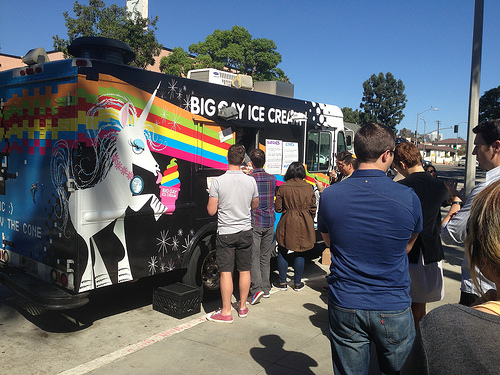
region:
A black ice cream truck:
[12, 48, 365, 317]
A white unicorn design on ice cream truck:
[44, 70, 173, 290]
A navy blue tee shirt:
[320, 164, 422, 321]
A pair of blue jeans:
[322, 300, 414, 374]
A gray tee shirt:
[214, 156, 254, 232]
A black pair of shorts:
[212, 230, 260, 275]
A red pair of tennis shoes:
[210, 301, 253, 327]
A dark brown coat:
[280, 176, 321, 257]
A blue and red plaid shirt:
[252, 170, 277, 231]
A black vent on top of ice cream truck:
[66, 29, 136, 62]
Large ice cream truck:
[9, 46, 361, 307]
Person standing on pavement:
[211, 126, 254, 327]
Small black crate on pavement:
[143, 276, 206, 324]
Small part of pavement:
[72, 334, 127, 371]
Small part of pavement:
[150, 342, 165, 358]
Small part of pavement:
[215, 349, 233, 371]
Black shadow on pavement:
[242, 323, 294, 374]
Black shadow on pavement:
[300, 294, 339, 340]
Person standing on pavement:
[321, 126, 420, 369]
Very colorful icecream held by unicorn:
[56, 82, 191, 299]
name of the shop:
[157, 83, 324, 131]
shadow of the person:
[247, 330, 316, 360]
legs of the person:
[206, 284, 279, 336]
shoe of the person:
[198, 300, 240, 328]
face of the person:
[341, 117, 411, 174]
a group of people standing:
[24, 62, 496, 372]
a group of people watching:
[178, 128, 340, 334]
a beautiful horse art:
[61, 106, 174, 297]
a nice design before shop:
[46, 83, 201, 287]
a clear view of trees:
[202, 30, 426, 141]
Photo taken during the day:
[32, 11, 484, 373]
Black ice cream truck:
[8, 73, 351, 303]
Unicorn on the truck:
[60, 75, 175, 305]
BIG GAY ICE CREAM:
[182, 85, 304, 140]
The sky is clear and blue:
[12, 0, 469, 137]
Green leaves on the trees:
[99, 2, 408, 117]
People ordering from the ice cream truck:
[195, 133, 320, 321]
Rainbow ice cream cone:
[154, 148, 189, 212]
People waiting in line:
[308, 140, 498, 363]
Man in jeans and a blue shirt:
[301, 117, 424, 373]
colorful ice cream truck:
[0, 34, 352, 314]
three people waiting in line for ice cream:
[201, 140, 321, 327]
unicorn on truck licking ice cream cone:
[67, 80, 185, 298]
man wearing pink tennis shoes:
[206, 300, 256, 328]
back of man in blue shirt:
[316, 124, 428, 374]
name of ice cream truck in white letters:
[187, 94, 312, 127]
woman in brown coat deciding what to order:
[273, 158, 321, 293]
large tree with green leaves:
[358, 78, 423, 123]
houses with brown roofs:
[416, 132, 472, 170]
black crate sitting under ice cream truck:
[148, 278, 210, 322]